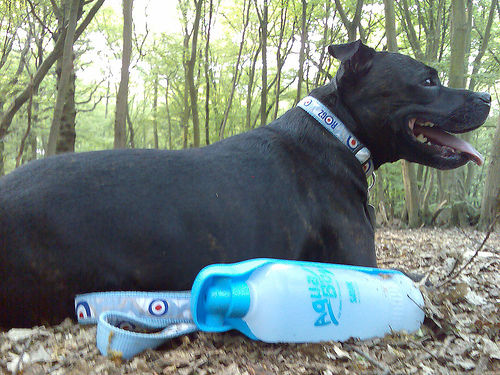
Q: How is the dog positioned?
A: It is sitting.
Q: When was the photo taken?
A: During the day.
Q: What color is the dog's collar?
A: Blue with a pattern.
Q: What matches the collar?
A: The leash.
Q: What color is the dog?
A: Black.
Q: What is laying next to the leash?
A: A water bottle.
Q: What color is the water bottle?
A: Blue.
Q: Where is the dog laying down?
A: In the woods.